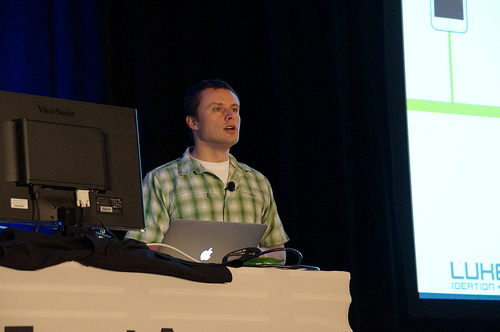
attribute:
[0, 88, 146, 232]
monitor — large, View Sonic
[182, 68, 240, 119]
hair — black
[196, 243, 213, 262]
logo — apple, lit up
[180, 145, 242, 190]
shirt — white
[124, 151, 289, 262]
shirt — guy's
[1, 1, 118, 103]
drapes — large, blue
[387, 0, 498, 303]
display — lcd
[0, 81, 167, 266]
monitor — black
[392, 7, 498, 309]
screen — big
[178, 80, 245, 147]
face — man's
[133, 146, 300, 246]
shirt — man's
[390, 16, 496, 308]
display — large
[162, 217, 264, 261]
computer — laptop, mac, apple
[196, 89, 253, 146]
man — young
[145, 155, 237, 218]
shirt — green, plaid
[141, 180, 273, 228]
shirt — button up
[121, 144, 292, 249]
shirt — striped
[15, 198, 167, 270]
cord — white, monitor cord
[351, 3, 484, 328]
screen — large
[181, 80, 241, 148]
head — man's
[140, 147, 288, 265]
shirt — green, plaid